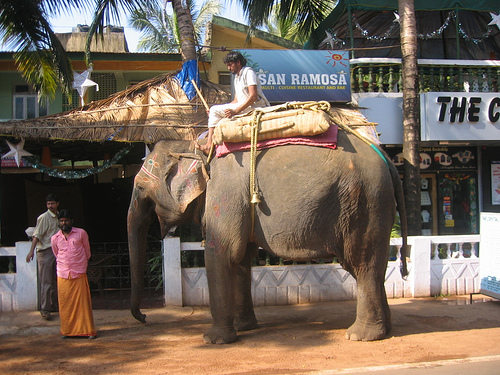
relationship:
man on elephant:
[194, 49, 270, 153] [127, 128, 409, 341]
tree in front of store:
[393, 2, 425, 239] [2, 55, 477, 150]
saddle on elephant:
[214, 99, 338, 150] [127, 128, 409, 341]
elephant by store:
[127, 128, 409, 341] [2, 55, 477, 150]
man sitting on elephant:
[194, 49, 270, 153] [127, 128, 409, 341]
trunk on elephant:
[124, 211, 153, 325] [127, 128, 409, 341]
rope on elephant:
[243, 114, 262, 253] [127, 128, 409, 341]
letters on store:
[433, 94, 500, 126] [2, 55, 477, 150]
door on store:
[435, 168, 481, 258] [2, 55, 477, 150]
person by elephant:
[47, 209, 99, 342] [127, 128, 409, 341]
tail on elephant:
[383, 153, 409, 283] [127, 128, 409, 341]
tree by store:
[393, 2, 425, 239] [2, 55, 477, 150]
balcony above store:
[349, 57, 498, 120] [2, 55, 477, 150]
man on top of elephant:
[194, 49, 270, 153] [127, 128, 409, 341]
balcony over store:
[349, 57, 498, 120] [2, 55, 477, 150]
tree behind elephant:
[393, 2, 425, 239] [127, 128, 409, 341]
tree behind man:
[393, 2, 425, 239] [194, 49, 270, 153]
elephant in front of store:
[127, 128, 409, 341] [2, 55, 477, 150]